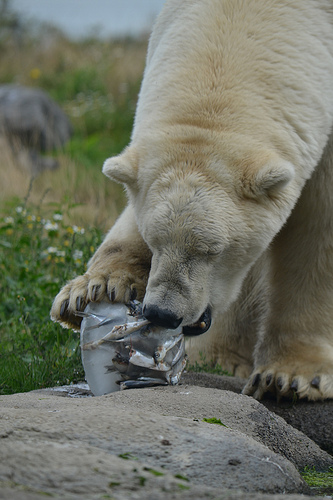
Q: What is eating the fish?
A: A white bear.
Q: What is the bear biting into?
A: Fish.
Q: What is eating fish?
A: A furry bear.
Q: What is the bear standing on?
A: Rock and grass.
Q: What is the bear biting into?
A: Frozen block of fish.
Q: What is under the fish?
A: A rock.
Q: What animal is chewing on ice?
A: Bear.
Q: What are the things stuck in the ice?
A: Fish.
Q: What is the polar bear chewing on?
A: A frozen block of fish.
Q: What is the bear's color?
A: White.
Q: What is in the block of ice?
A: Fish.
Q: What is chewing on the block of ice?
A: Polar bear.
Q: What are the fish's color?
A: White.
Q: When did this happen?
A: During the day time.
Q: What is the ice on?
A: Rock.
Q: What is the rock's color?
A: Gray.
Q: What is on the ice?
A: A claw.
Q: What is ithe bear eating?
A: Fish.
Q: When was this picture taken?
A: As a polar bear was being fed.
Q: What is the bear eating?
A: Frozen fish.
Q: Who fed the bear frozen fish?
A: A Zookeeper.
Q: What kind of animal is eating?
A: A Bear.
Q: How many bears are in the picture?
A: One bear.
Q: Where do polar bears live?
A: In the Arctic.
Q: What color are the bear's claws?
A: Black.